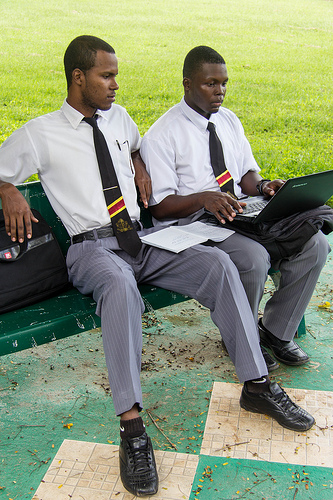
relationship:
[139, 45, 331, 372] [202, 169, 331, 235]
man using laptop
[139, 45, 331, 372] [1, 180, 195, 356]
man on bench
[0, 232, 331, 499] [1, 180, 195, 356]
concrete around bench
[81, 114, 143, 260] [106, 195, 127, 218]
tie has stripe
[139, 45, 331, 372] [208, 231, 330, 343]
man wearing pants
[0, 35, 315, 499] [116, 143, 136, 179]
man has pocket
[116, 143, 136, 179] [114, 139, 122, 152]
pocket holds pen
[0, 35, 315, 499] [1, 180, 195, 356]
man on bench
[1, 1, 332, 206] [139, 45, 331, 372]
field behind man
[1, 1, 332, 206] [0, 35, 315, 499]
field behind man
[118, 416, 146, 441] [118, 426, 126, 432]
sock has emblem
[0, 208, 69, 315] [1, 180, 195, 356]
bag on top of bench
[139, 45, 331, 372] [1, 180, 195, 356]
man sitting on bench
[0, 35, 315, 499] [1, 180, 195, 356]
man sitting on bench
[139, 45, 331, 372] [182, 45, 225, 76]
man has hair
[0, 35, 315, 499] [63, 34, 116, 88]
man has hair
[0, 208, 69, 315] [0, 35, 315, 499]
bag next to man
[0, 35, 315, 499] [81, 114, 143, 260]
man wearing tie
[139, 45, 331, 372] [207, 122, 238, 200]
man wearing tie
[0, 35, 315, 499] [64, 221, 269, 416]
man wearing pants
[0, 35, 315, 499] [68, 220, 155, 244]
man wearing belt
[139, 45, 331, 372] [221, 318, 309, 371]
man wearing shoes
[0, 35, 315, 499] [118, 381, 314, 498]
man wearing shoes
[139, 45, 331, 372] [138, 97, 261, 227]
man wearing shirt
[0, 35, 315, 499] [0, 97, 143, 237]
man wearing shirt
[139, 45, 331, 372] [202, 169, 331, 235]
man holding laptop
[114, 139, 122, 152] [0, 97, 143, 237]
pen in shirt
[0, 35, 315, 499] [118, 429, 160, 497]
man wearing shoe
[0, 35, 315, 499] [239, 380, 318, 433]
man wearing shoe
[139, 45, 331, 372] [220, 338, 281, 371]
man wearing shoe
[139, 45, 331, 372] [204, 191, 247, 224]
man has hand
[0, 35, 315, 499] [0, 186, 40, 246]
man has hand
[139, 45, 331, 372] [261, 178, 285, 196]
man has hand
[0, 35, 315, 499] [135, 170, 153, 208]
man has hand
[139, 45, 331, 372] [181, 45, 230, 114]
man has head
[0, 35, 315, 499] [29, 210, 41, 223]
man has thumb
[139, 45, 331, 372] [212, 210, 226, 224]
man has finger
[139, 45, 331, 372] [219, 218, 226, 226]
man has fingernail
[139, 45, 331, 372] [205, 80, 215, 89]
man has eye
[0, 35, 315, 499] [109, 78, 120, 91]
man has nose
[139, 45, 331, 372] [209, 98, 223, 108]
man has mouth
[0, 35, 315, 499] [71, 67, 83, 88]
man has ear